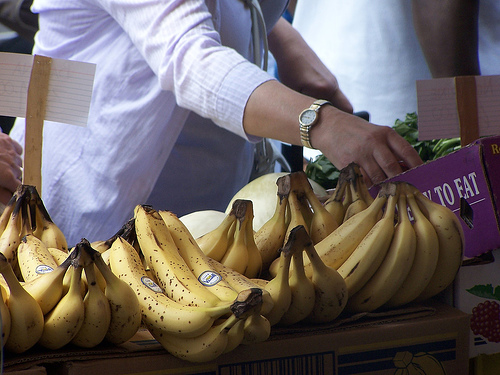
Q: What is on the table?
A: Bananas.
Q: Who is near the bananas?
A: A person.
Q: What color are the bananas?
A: Yellow.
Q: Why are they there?
A: To sell.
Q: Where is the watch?
A: On the wrist.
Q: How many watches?
A: 1.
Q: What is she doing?
A: Shopping.